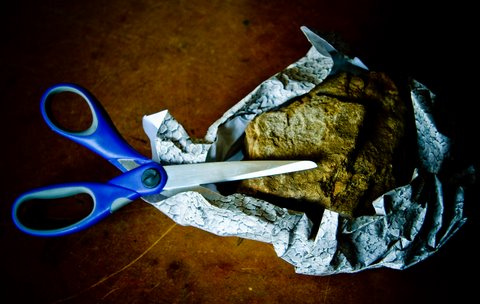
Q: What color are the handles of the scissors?
A: Blue.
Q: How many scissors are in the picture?
A: One.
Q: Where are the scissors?
A: On the table.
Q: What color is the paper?
A: White.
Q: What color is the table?
A: Brown.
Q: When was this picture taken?
A: During the day.